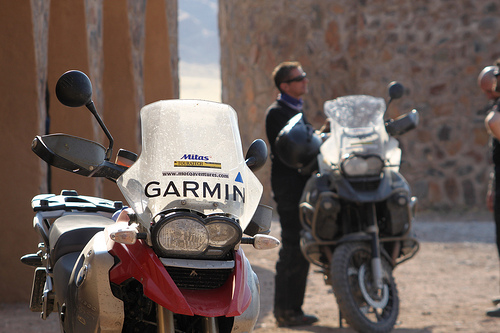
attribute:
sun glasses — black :
[280, 70, 310, 84]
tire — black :
[327, 226, 408, 329]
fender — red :
[104, 234, 272, 327]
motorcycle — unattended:
[33, 66, 280, 330]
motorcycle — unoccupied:
[26, 52, 264, 327]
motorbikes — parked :
[36, 60, 427, 321]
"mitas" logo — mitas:
[171, 144, 228, 181]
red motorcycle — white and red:
[104, 232, 272, 317]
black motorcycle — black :
[289, 99, 439, 331]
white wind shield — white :
[113, 102, 263, 231]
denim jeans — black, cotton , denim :
[268, 192, 334, 329]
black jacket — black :
[258, 93, 313, 211]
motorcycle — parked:
[290, 118, 411, 331]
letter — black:
[227, 181, 252, 202]